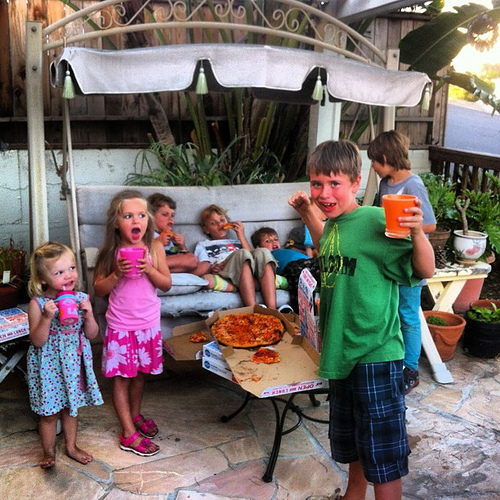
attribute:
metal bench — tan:
[23, 0, 454, 438]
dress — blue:
[30, 290, 100, 415]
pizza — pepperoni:
[212, 309, 286, 352]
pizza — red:
[187, 309, 284, 365]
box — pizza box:
[209, 304, 326, 398]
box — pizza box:
[198, 334, 230, 364]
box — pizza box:
[198, 355, 242, 385]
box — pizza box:
[293, 268, 323, 348]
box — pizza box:
[163, 309, 219, 365]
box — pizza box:
[1, 303, 33, 343]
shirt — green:
[300, 205, 407, 362]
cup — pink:
[113, 252, 165, 289]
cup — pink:
[51, 283, 84, 328]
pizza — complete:
[198, 304, 335, 406]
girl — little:
[22, 235, 114, 477]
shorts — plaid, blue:
[322, 357, 414, 484]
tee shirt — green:
[308, 203, 417, 382]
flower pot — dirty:
[420, 303, 464, 362]